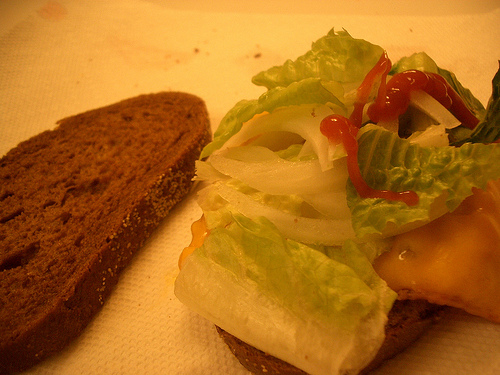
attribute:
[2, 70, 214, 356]
bread — brown, dark, sliced, holey, dry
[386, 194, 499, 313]
cheese — sliced, sticking, melted, yellow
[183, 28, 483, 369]
lettuce — green, white, jagged, piled, fresh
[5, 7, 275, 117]
cloth — white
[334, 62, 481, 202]
ketchup — red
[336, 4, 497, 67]
napkin — white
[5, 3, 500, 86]
towel — white